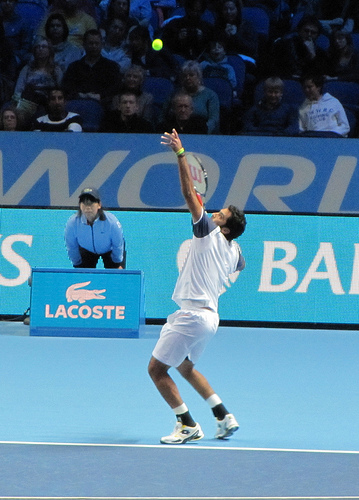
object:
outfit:
[151, 204, 247, 378]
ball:
[150, 37, 164, 54]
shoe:
[160, 421, 205, 446]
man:
[148, 126, 248, 455]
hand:
[159, 128, 185, 155]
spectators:
[295, 66, 350, 138]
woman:
[63, 185, 127, 271]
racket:
[180, 153, 208, 214]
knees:
[146, 359, 155, 380]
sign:
[31, 271, 140, 340]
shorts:
[151, 304, 220, 370]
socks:
[172, 400, 197, 429]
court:
[0, 316, 359, 499]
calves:
[175, 364, 216, 402]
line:
[0, 441, 359, 457]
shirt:
[170, 200, 248, 312]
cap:
[78, 186, 102, 204]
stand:
[0, 0, 359, 213]